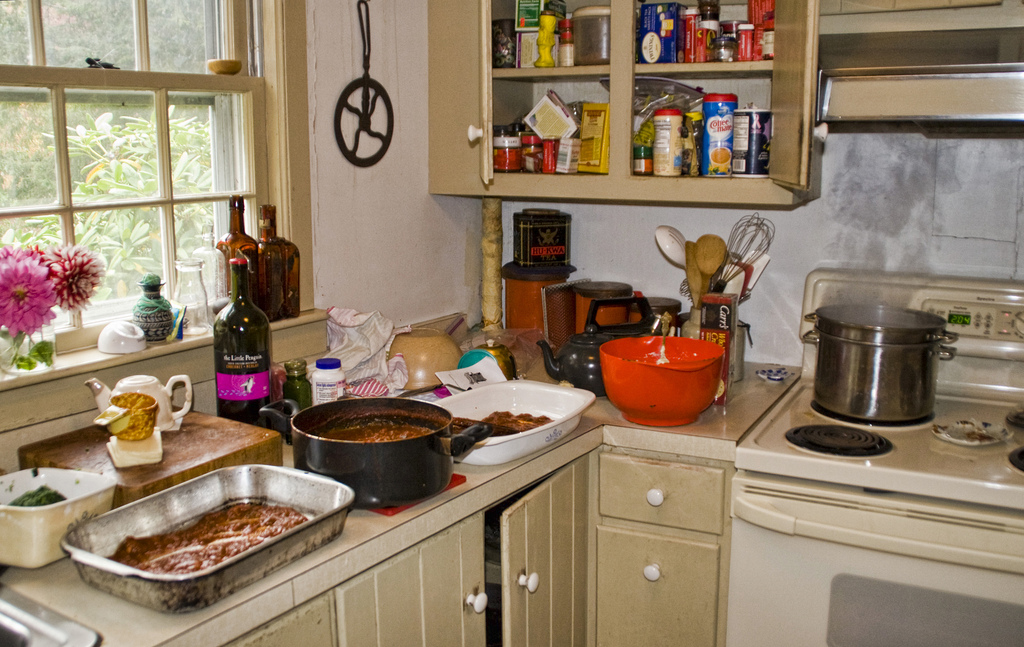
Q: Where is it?
A: This is at the kitchen.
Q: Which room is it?
A: It is a kitchen.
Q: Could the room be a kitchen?
A: Yes, it is a kitchen.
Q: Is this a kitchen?
A: Yes, it is a kitchen.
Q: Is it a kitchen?
A: Yes, it is a kitchen.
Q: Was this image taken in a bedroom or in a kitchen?
A: It was taken at a kitchen.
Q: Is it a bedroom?
A: No, it is a kitchen.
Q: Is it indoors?
A: Yes, it is indoors.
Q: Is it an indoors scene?
A: Yes, it is indoors.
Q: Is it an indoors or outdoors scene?
A: It is indoors.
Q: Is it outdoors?
A: No, it is indoors.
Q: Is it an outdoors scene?
A: No, it is indoors.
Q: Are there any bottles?
A: Yes, there is a bottle.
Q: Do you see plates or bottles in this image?
A: Yes, there is a bottle.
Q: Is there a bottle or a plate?
A: Yes, there is a bottle.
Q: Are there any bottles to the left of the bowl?
A: Yes, there is a bottle to the left of the bowl.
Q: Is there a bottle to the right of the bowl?
A: No, the bottle is to the left of the bowl.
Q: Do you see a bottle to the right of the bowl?
A: No, the bottle is to the left of the bowl.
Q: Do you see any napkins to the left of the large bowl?
A: No, there is a bottle to the left of the bowl.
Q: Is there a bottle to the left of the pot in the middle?
A: Yes, there is a bottle to the left of the pot.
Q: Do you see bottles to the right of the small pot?
A: No, the bottle is to the left of the pot.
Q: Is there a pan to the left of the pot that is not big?
A: No, there is a bottle to the left of the pot.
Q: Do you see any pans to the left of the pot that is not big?
A: No, there is a bottle to the left of the pot.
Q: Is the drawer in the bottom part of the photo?
A: Yes, the drawer is in the bottom of the image.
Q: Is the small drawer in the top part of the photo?
A: No, the drawer is in the bottom of the image.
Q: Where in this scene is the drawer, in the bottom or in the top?
A: The drawer is in the bottom of the image.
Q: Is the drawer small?
A: Yes, the drawer is small.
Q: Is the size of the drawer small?
A: Yes, the drawer is small.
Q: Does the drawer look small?
A: Yes, the drawer is small.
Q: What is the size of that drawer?
A: The drawer is small.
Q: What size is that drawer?
A: The drawer is small.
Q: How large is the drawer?
A: The drawer is small.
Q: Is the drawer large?
A: No, the drawer is small.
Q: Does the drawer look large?
A: No, the drawer is small.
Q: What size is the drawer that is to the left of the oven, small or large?
A: The drawer is small.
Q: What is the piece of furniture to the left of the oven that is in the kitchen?
A: The piece of furniture is a drawer.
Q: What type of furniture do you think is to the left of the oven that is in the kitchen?
A: The piece of furniture is a drawer.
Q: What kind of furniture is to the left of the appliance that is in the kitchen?
A: The piece of furniture is a drawer.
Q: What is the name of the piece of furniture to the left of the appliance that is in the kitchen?
A: The piece of furniture is a drawer.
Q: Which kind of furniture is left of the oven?
A: The piece of furniture is a drawer.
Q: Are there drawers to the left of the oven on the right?
A: Yes, there is a drawer to the left of the oven.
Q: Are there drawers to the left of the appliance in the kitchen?
A: Yes, there is a drawer to the left of the oven.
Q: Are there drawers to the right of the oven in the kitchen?
A: No, the drawer is to the left of the oven.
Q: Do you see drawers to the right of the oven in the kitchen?
A: No, the drawer is to the left of the oven.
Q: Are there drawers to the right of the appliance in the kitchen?
A: No, the drawer is to the left of the oven.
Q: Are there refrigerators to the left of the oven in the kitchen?
A: No, there is a drawer to the left of the oven.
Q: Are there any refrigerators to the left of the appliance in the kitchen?
A: No, there is a drawer to the left of the oven.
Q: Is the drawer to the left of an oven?
A: Yes, the drawer is to the left of an oven.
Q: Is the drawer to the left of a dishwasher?
A: No, the drawer is to the left of an oven.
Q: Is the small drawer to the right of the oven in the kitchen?
A: No, the drawer is to the left of the oven.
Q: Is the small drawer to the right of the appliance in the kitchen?
A: No, the drawer is to the left of the oven.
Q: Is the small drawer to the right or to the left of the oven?
A: The drawer is to the left of the oven.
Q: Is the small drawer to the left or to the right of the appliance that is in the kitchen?
A: The drawer is to the left of the oven.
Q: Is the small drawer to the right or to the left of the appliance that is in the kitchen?
A: The drawer is to the left of the oven.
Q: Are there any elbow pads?
A: No, there are no elbow pads.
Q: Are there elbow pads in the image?
A: No, there are no elbow pads.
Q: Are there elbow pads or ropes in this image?
A: No, there are no elbow pads or ropes.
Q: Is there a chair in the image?
A: No, there are no chairs.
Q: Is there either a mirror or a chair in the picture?
A: No, there are no chairs or mirrors.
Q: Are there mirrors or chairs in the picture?
A: No, there are no chairs or mirrors.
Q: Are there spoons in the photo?
A: Yes, there is a spoon.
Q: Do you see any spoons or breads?
A: Yes, there is a spoon.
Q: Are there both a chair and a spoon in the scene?
A: No, there is a spoon but no chairs.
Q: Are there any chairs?
A: No, there are no chairs.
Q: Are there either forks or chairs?
A: No, there are no chairs or forks.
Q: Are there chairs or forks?
A: No, there are no chairs or forks.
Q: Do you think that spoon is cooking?
A: Yes, the spoon is cooking.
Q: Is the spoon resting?
A: No, the spoon is cooking.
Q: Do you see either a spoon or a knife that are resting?
A: No, there is a spoon but it is cooking.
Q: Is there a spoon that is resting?
A: No, there is a spoon but it is cooking.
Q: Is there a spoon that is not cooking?
A: No, there is a spoon but it is cooking.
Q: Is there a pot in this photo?
A: Yes, there is a pot.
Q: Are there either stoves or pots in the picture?
A: Yes, there is a pot.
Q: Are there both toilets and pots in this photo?
A: No, there is a pot but no toilets.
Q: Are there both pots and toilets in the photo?
A: No, there is a pot but no toilets.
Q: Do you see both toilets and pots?
A: No, there is a pot but no toilets.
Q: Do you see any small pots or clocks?
A: Yes, there is a small pot.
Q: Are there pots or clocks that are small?
A: Yes, the pot is small.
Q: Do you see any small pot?
A: Yes, there is a small pot.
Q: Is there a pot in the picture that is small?
A: Yes, there is a pot that is small.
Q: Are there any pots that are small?
A: Yes, there is a pot that is small.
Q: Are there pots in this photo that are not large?
A: Yes, there is a small pot.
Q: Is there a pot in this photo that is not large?
A: Yes, there is a small pot.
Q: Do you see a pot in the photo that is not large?
A: Yes, there is a small pot.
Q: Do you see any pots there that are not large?
A: Yes, there is a small pot.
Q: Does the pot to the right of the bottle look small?
A: Yes, the pot is small.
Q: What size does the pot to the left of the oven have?
A: The pot has small size.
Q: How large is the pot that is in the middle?
A: The pot is small.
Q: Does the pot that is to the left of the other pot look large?
A: No, the pot is small.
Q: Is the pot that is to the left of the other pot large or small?
A: The pot is small.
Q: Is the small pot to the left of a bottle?
A: No, the pot is to the right of a bottle.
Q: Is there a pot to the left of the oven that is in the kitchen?
A: Yes, there is a pot to the left of the oven.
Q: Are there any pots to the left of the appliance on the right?
A: Yes, there is a pot to the left of the oven.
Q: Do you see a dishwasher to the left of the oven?
A: No, there is a pot to the left of the oven.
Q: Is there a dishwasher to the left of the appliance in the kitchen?
A: No, there is a pot to the left of the oven.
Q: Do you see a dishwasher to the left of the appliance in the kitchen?
A: No, there is a pot to the left of the oven.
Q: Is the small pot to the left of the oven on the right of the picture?
A: Yes, the pot is to the left of the oven.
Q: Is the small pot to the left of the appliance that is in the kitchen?
A: Yes, the pot is to the left of the oven.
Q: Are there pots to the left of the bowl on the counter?
A: Yes, there is a pot to the left of the bowl.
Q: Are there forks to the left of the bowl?
A: No, there is a pot to the left of the bowl.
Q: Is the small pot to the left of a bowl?
A: Yes, the pot is to the left of a bowl.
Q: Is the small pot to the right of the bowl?
A: No, the pot is to the left of the bowl.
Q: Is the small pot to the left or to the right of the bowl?
A: The pot is to the left of the bowl.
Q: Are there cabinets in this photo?
A: Yes, there is a cabinet.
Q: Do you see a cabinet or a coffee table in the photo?
A: Yes, there is a cabinet.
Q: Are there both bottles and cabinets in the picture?
A: Yes, there are both a cabinet and a bottle.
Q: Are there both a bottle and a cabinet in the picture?
A: Yes, there are both a cabinet and a bottle.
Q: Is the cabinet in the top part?
A: Yes, the cabinet is in the top of the image.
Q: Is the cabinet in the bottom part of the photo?
A: No, the cabinet is in the top of the image.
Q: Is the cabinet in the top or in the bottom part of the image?
A: The cabinet is in the top of the image.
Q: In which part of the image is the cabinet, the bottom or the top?
A: The cabinet is in the top of the image.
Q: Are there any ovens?
A: Yes, there is an oven.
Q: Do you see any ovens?
A: Yes, there is an oven.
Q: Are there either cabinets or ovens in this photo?
A: Yes, there is an oven.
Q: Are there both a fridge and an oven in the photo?
A: No, there is an oven but no refrigerators.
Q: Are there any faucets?
A: No, there are no faucets.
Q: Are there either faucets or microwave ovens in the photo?
A: No, there are no faucets or microwave ovens.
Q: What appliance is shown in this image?
A: The appliance is an oven.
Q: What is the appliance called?
A: The appliance is an oven.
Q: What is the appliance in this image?
A: The appliance is an oven.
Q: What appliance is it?
A: The appliance is an oven.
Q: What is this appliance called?
A: This is an oven.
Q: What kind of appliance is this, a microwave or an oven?
A: This is an oven.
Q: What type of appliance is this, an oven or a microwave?
A: This is an oven.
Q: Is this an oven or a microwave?
A: This is an oven.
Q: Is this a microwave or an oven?
A: This is an oven.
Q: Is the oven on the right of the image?
A: Yes, the oven is on the right of the image.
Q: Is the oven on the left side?
A: No, the oven is on the right of the image.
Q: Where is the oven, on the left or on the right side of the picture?
A: The oven is on the right of the image.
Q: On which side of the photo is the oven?
A: The oven is on the right of the image.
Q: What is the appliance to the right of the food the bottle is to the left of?
A: The appliance is an oven.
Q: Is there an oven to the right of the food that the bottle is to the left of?
A: Yes, there is an oven to the right of the food.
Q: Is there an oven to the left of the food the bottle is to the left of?
A: No, the oven is to the right of the food.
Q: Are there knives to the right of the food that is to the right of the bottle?
A: No, there is an oven to the right of the food.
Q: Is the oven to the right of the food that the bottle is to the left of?
A: Yes, the oven is to the right of the food.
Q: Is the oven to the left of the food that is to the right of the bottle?
A: No, the oven is to the right of the food.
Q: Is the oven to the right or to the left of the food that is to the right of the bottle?
A: The oven is to the right of the food.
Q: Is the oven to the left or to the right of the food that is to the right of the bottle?
A: The oven is to the right of the food.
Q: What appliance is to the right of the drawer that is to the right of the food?
A: The appliance is an oven.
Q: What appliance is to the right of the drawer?
A: The appliance is an oven.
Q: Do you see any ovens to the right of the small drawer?
A: Yes, there is an oven to the right of the drawer.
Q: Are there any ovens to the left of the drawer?
A: No, the oven is to the right of the drawer.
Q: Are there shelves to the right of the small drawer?
A: No, there is an oven to the right of the drawer.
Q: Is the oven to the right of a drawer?
A: Yes, the oven is to the right of a drawer.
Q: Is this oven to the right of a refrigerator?
A: No, the oven is to the right of a drawer.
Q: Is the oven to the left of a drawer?
A: No, the oven is to the right of a drawer.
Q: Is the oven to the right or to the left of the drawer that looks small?
A: The oven is to the right of the drawer.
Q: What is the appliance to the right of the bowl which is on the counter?
A: The appliance is an oven.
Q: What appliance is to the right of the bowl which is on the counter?
A: The appliance is an oven.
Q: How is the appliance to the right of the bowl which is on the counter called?
A: The appliance is an oven.